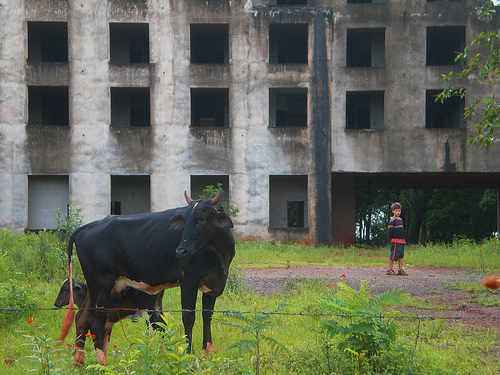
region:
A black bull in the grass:
[61, 193, 233, 363]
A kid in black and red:
[384, 198, 409, 277]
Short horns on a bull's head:
[182, 187, 223, 204]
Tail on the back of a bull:
[56, 223, 86, 348]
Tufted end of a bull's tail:
[56, 303, 72, 343]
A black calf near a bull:
[54, 271, 166, 352]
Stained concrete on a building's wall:
[267, 132, 311, 174]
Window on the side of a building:
[189, 87, 229, 131]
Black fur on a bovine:
[110, 228, 174, 281]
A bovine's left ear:
[211, 207, 233, 229]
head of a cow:
[173, 179, 245, 264]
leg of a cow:
[203, 281, 228, 338]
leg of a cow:
[180, 276, 204, 325]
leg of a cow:
[99, 310, 110, 341]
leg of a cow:
[65, 321, 102, 364]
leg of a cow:
[136, 317, 183, 361]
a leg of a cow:
[200, 294, 221, 346]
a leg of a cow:
[180, 296, 202, 336]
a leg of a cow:
[89, 298, 113, 353]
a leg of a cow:
[60, 307, 85, 373]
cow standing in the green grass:
[40, 181, 241, 371]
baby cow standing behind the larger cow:
[47, 241, 184, 349]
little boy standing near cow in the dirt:
[367, 193, 422, 292]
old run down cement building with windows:
[254, 1, 327, 246]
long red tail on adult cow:
[55, 243, 79, 347]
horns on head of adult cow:
[173, 178, 235, 236]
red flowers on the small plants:
[12, 305, 55, 374]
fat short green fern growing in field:
[313, 278, 416, 368]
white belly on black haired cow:
[108, 258, 224, 305]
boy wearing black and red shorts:
[382, 233, 413, 273]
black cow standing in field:
[67, 192, 239, 344]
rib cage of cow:
[138, 220, 172, 257]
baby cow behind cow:
[42, 291, 191, 341]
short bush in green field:
[321, 300, 397, 349]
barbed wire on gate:
[276, 307, 338, 332]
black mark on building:
[314, 88, 349, 123]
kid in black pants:
[389, 237, 413, 281]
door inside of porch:
[281, 198, 311, 229]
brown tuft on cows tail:
[58, 298, 81, 352]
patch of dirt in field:
[296, 270, 341, 305]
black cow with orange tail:
[54, 185, 248, 365]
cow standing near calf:
[48, 184, 243, 374]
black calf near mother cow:
[48, 268, 175, 351]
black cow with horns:
[50, 179, 241, 369]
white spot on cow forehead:
[188, 194, 201, 214]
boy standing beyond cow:
[380, 197, 409, 279]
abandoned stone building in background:
[2, 2, 498, 240]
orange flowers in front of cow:
[0, 309, 225, 374]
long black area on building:
[307, 8, 341, 248]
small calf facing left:
[50, 272, 175, 354]